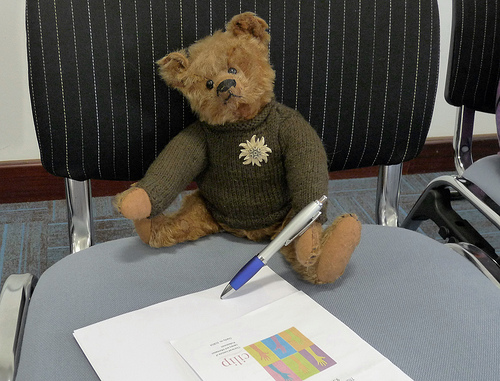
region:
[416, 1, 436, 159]
white dotted line on chair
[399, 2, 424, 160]
white dotted line on chair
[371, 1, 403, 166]
white dotted line on chair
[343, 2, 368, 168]
white dotted line on chair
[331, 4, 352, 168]
white dotted line on chair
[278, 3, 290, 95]
white dotted line on chair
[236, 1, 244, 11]
white dotted line on chair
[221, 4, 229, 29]
white dotted line on chair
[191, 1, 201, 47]
white dotted line on chair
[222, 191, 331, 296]
silver and blue pen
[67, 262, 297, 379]
plain white paper on seat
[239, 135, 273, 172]
yellow flower on sweater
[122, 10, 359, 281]
cute brown teddy bear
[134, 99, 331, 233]
green wool teddy sweater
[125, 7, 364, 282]
bear wearing a green sweater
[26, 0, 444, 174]
black pin striped cushion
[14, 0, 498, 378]
black and blue chair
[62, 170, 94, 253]
shiny silver metal support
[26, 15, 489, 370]
teddy bear sitting in an office chair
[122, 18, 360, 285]
teddy bear wearing a brown sweater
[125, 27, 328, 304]
teddy bear holding a pen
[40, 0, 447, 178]
black pinstriped fabric on back of chair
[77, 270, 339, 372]
papers on the seat of the chair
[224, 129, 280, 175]
white brooch on bears sweater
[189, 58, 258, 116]
teddy bear with black eyes and nose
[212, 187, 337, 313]
silver and blue pen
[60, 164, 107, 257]
silver frame of chair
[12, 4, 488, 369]
two office chairs next to each other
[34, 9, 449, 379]
Teddy bear sitting in a chair.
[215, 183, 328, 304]
A silver and blue ink pen.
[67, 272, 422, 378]
Papers laying in a chair.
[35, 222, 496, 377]
Grey chair cushion.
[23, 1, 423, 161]
Back of chair is black with white stripes.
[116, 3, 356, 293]
Teddy bear "holding" an ink pen.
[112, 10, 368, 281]
Teddy bear wearing a sweater.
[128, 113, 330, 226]
A small long sleeve sweater.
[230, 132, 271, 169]
A tan design on sweater.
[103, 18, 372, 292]
A brown teddy bear.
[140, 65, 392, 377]
The teddy bear is on the chair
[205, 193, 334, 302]
The pen is on the chair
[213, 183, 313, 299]
The pen is blue and gray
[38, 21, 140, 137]
The chair is pinstriped black and white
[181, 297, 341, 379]
The graphics on the paper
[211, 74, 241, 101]
The nose of the teddy bear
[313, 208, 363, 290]
The foot of the teddy bear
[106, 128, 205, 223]
The arm of the teddy bear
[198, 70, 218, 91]
The eye of the teddy bear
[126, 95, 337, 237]
The teddy bear has on a sweater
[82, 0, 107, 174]
white line on the chair back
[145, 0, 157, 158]
white line on the chair back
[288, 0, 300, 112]
white line on the chair back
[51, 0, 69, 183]
white line on the black chair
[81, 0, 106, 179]
white line on the black chair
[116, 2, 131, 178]
white line on the black chair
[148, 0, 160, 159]
white line on the black chair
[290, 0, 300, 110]
white line on the black chair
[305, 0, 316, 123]
white line on the black chair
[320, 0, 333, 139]
white line on the black chair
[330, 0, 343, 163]
white line on the black chair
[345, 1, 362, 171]
white line on the black chair